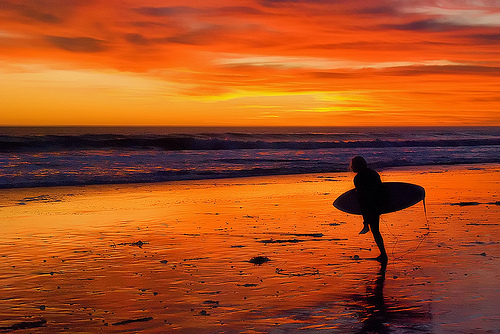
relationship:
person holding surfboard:
[349, 153, 390, 262] [332, 181, 425, 217]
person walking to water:
[349, 153, 390, 262] [0, 123, 499, 187]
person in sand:
[349, 153, 390, 262] [0, 162, 500, 334]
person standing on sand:
[349, 153, 390, 262] [0, 162, 500, 334]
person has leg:
[349, 153, 390, 262] [368, 210, 390, 262]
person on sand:
[349, 153, 390, 262] [0, 162, 500, 334]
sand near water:
[0, 162, 500, 334] [0, 123, 499, 187]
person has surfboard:
[349, 153, 390, 262] [332, 181, 425, 217]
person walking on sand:
[349, 153, 390, 262] [0, 162, 500, 334]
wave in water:
[0, 131, 496, 151] [0, 123, 499, 187]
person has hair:
[349, 153, 390, 262] [349, 153, 369, 175]